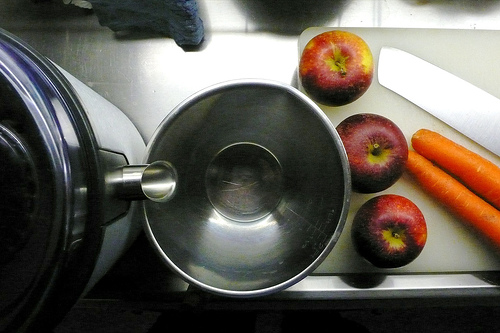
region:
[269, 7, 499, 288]
Red apples and orange carrots.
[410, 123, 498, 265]
Two orange carrots.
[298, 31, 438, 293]
Three red apples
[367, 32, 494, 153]
A silver knife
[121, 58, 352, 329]
A silver bowl next to apples and carrots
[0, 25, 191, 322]
A juicer with its spout above a bowl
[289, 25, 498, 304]
Apples and carrots on a cutting board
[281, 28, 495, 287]
Apples and carrots next to a juicer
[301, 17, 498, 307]
Apples and carrots on a cutting board next to a silver bowl.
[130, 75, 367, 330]
Silver bowl below a juicer.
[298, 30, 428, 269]
a group of three apples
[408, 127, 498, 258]
two carrots on a cutting board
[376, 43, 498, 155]
a large metal knife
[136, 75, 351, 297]
an empty metal bowl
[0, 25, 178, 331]
an electric juicing machine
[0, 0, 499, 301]
a large metal surface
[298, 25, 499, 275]
a white plastic cutting board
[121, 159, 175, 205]
metal spout on juicer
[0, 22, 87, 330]
plastic top of juicer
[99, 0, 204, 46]
a folded blue cloth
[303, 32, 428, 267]
apples are on cutting board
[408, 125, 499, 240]
carrots are very orange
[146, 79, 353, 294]
silver bowl on table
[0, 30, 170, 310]
juicer will be used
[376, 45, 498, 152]
knife is on cutting board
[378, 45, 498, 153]
knife is silver and shape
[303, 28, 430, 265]
there are 3 apples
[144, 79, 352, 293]
silver bowl is deep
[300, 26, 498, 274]
cutting board is white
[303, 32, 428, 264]
apples are red and white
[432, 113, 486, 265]
Orange carrots on the table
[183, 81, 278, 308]
silver bowl sitting on table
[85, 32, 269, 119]
silver surface below the bowl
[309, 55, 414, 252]
Red apples on counter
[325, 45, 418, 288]
Three apples sitting on counter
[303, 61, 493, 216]
Apples and carrots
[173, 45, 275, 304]
a silver bowl on the table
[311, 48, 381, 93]
red apple with green on it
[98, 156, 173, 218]
silver nozzle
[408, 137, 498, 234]
Two carrots on the table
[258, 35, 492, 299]
Apples are in the photo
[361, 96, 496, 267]
Carrots are in the photo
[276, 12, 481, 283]
Carrots and apples are on a cutting board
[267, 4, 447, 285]
Three apples are in the photo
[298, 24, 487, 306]
Three apples are on a cutting board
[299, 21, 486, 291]
A knife is on the cutting board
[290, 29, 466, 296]
A knife is near the carrots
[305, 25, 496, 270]
Three apples are near a knife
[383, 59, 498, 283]
Two carrots are in the photo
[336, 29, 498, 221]
Two carrots are next to a knife